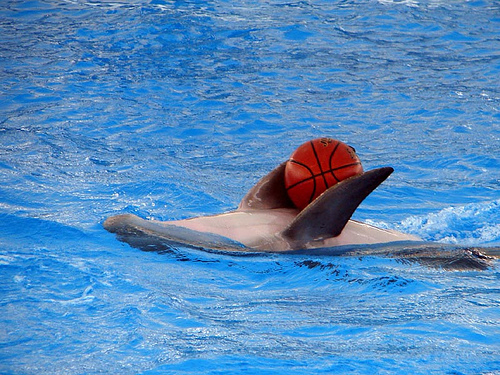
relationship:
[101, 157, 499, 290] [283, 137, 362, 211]
dolphin has basketball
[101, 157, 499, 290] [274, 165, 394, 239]
dolphin has flipper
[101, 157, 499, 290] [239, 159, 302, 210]
dolphin has flipper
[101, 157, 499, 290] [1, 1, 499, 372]
dolphin in water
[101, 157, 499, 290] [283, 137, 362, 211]
dolphin holding basketball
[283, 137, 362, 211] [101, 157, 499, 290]
basketball held by dolphin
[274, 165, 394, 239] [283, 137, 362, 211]
flipper holding basketball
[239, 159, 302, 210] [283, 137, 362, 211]
flipper holding basketball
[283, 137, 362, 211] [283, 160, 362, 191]
basketball has stripe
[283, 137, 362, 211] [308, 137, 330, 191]
basketball has stripe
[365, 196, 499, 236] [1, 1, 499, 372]
wave in water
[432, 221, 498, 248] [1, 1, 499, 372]
wave in water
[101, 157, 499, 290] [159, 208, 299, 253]
dolphin has chest